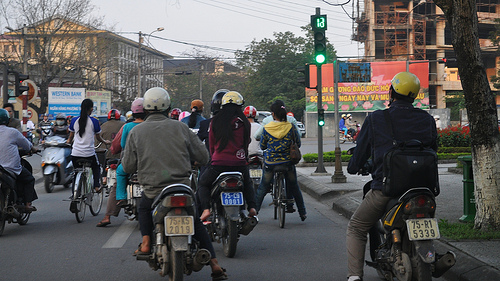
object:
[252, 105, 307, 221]
woman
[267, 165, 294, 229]
bike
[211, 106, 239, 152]
hair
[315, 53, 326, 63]
light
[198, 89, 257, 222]
couple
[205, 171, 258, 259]
motorcycle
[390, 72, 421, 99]
helmet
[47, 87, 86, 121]
sign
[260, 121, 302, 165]
hoodie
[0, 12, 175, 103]
building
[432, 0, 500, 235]
tree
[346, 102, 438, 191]
jacket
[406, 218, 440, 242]
license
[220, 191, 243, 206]
plate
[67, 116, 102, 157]
shirt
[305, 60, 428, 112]
sign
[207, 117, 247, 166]
sweater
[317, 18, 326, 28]
numbers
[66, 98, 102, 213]
woman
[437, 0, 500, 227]
trunk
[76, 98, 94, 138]
hair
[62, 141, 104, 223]
bike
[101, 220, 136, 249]
line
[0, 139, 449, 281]
road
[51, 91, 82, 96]
writing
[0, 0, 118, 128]
tree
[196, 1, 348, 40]
wires